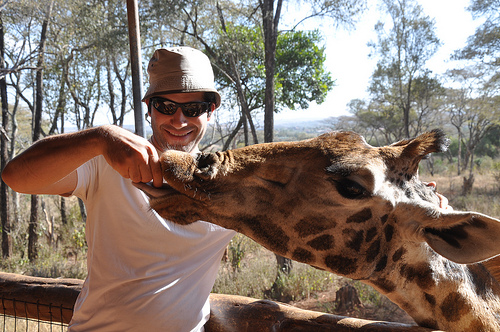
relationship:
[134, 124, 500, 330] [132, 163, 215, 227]
giraffe has mouth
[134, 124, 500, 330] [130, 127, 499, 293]
giraffe has head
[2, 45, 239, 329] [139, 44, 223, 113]
man inside of hat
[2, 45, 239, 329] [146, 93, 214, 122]
man inside of sunglasses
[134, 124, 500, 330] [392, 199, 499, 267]
giraffe has ear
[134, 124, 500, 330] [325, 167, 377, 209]
giraffe has eye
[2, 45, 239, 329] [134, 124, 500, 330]
man feeding giraffe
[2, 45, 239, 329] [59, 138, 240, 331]
man wearing t-shirt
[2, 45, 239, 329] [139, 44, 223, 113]
man wearing hat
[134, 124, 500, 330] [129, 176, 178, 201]
giraffe has tongue